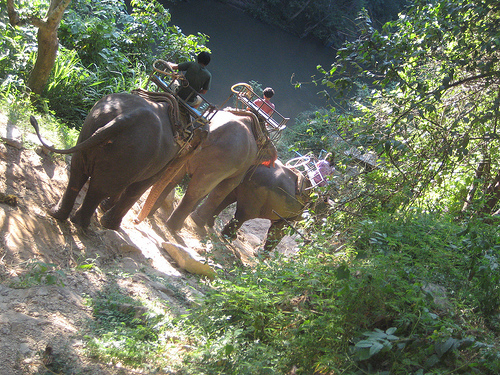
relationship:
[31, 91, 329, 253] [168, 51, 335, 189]
elephants carrying passengers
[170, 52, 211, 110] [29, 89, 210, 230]
man on elephant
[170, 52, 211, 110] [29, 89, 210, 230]
man riding elephant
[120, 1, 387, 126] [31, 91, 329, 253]
river near elephants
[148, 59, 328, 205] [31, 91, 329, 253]
chairs on elephants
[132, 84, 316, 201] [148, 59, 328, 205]
blankets under chairs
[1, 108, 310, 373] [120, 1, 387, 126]
dirt near river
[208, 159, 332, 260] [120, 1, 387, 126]
elephant closest to river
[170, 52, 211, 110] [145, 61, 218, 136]
man sitting in chair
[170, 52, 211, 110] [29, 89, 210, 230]
man riding on elephant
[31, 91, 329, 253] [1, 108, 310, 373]
elephants on dirt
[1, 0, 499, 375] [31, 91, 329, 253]
leaves around elephants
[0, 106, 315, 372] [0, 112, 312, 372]
ground has rocks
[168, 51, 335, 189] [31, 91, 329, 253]
passengers riding elephants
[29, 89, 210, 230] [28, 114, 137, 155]
elephant has a tail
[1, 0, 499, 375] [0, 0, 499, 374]
leaves on trees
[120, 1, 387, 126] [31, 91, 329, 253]
river in front of elephants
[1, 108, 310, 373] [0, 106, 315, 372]
dirt on ground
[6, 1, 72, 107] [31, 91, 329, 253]
trunk near elephants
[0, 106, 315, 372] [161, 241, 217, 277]
ground under pillow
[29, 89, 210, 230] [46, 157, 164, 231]
elephant has legs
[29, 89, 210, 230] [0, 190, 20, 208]
elephant dropped feces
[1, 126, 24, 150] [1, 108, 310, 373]
rock on dirt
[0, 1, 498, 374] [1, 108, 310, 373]
greenery around dirt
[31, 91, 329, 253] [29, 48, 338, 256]
elephants in a row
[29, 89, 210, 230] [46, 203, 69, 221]
elephant has a foot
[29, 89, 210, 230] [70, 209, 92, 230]
elephant has a foot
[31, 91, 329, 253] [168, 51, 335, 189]
elephants giving rides to passengers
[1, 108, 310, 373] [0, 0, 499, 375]
dirt in woods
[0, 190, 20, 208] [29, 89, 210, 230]
feces from elephant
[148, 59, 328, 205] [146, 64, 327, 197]
chairs made of wood